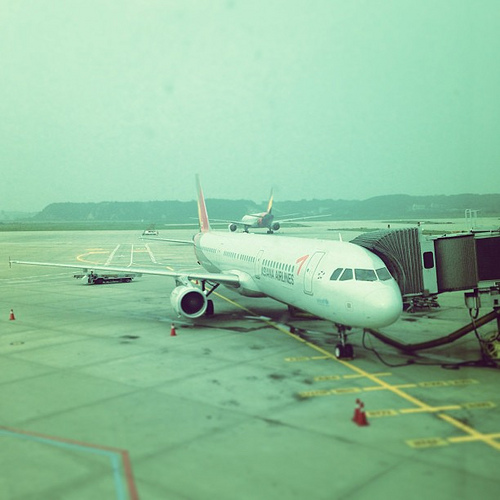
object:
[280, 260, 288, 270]
window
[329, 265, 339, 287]
window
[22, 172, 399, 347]
vehicle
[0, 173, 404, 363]
plane